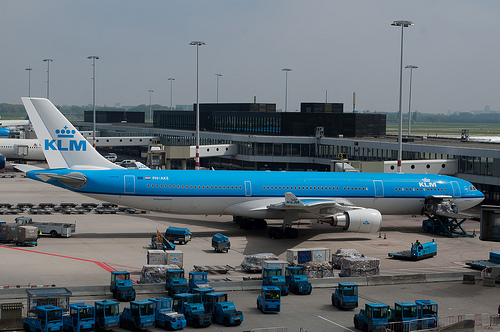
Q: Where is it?
A: This is at the airport.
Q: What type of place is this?
A: It is an airport.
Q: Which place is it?
A: It is an airport.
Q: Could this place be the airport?
A: Yes, it is the airport.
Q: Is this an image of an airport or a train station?
A: It is showing an airport.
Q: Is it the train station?
A: No, it is the airport.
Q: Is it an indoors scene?
A: Yes, it is indoors.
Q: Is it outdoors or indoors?
A: It is indoors.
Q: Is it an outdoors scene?
A: No, it is indoors.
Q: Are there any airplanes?
A: Yes, there is an airplane.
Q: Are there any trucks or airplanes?
A: Yes, there is an airplane.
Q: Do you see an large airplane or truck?
A: Yes, there is a large airplane.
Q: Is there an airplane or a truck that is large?
A: Yes, the airplane is large.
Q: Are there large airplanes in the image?
A: Yes, there is a large airplane.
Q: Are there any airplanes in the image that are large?
A: Yes, there is an airplane that is large.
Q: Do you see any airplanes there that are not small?
A: Yes, there is a large airplane.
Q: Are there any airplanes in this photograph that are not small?
A: Yes, there is a large airplane.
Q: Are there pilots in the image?
A: No, there are no pilots.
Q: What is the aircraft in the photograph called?
A: The aircraft is an airplane.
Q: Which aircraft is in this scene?
A: The aircraft is an airplane.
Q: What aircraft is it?
A: The aircraft is an airplane.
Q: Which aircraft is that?
A: This is an airplane.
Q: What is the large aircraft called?
A: The aircraft is an airplane.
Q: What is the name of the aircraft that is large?
A: The aircraft is an airplane.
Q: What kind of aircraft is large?
A: The aircraft is an airplane.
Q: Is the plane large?
A: Yes, the plane is large.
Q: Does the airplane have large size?
A: Yes, the airplane is large.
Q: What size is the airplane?
A: The airplane is large.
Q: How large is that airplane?
A: The airplane is large.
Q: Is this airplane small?
A: No, the airplane is large.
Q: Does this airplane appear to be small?
A: No, the airplane is large.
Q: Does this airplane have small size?
A: No, the airplane is large.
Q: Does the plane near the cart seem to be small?
A: No, the airplane is large.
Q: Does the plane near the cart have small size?
A: No, the airplane is large.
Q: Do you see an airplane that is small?
A: No, there is an airplane but it is large.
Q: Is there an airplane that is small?
A: No, there is an airplane but it is large.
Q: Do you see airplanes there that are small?
A: No, there is an airplane but it is large.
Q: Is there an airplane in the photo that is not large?
A: No, there is an airplane but it is large.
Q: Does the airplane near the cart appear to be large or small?
A: The plane is large.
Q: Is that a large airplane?
A: Yes, that is a large airplane.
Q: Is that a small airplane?
A: No, that is a large airplane.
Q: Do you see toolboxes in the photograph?
A: No, there are no toolboxes.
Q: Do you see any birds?
A: No, there are no birds.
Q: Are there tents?
A: No, there are no tents.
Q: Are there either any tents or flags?
A: No, there are no tents or flags.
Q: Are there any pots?
A: No, there are no pots.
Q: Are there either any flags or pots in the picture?
A: No, there are no pots or flags.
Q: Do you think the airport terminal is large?
A: Yes, the terminal is large.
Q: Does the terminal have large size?
A: Yes, the terminal is large.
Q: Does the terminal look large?
A: Yes, the terminal is large.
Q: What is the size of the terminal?
A: The terminal is large.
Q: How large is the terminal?
A: The terminal is large.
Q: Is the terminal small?
A: No, the terminal is large.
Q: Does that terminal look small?
A: No, the terminal is large.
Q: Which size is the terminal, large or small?
A: The terminal is large.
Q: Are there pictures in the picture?
A: No, there are no pictures.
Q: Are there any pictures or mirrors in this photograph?
A: No, there are no pictures or mirrors.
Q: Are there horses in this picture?
A: No, there are no horses.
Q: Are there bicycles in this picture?
A: No, there are no bicycles.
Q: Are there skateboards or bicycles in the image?
A: No, there are no bicycles or skateboards.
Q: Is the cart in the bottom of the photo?
A: Yes, the cart is in the bottom of the image.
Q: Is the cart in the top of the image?
A: No, the cart is in the bottom of the image.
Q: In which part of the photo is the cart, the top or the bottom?
A: The cart is in the bottom of the image.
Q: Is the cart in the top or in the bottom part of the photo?
A: The cart is in the bottom of the image.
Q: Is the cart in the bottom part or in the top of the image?
A: The cart is in the bottom of the image.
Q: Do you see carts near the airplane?
A: Yes, there is a cart near the airplane.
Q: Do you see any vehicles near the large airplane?
A: No, there is a cart near the airplane.